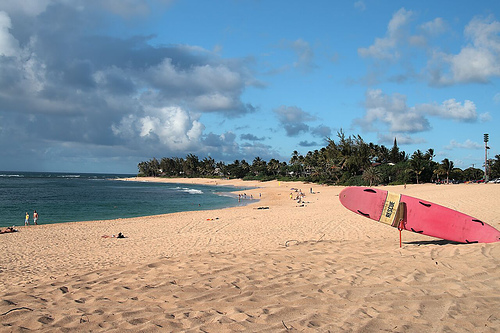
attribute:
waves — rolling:
[173, 184, 202, 198]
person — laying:
[2, 224, 18, 238]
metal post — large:
[483, 142, 490, 184]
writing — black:
[382, 193, 399, 219]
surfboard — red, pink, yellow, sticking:
[338, 182, 499, 244]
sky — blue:
[1, 0, 499, 175]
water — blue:
[2, 169, 264, 238]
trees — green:
[295, 136, 420, 188]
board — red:
[424, 212, 474, 234]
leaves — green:
[289, 121, 459, 195]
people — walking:
[18, 207, 39, 224]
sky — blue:
[168, 2, 385, 60]